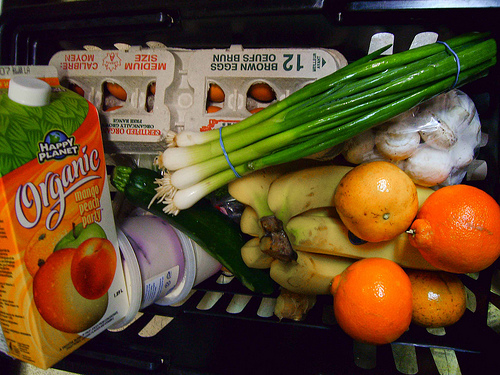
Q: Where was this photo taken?
A: Grocery store.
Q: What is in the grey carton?
A: Eggs.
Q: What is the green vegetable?
A: Onions.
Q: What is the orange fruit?
A: Oranges.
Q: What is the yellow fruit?
A: Bananas.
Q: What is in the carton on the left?
A: Juice.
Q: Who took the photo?
A: Shopper.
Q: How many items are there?
A: Eleven.